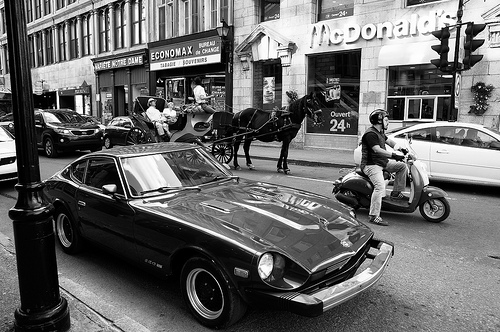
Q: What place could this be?
A: It is a city.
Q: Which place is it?
A: It is a city.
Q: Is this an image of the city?
A: Yes, it is showing the city.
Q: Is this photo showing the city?
A: Yes, it is showing the city.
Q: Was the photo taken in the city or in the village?
A: It was taken at the city.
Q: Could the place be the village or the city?
A: It is the city.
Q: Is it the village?
A: No, it is the city.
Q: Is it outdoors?
A: Yes, it is outdoors.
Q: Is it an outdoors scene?
A: Yes, it is outdoors.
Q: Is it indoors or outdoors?
A: It is outdoors.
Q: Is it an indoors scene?
A: No, it is outdoors.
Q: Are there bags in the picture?
A: No, there are no bags.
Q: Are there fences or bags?
A: No, there are no bags or fences.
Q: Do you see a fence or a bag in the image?
A: No, there are no bags or fences.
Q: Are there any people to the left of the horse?
A: Yes, there is a person to the left of the horse.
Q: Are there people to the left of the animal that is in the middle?
A: Yes, there is a person to the left of the horse.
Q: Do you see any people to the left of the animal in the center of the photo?
A: Yes, there is a person to the left of the horse.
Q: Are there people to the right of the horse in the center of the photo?
A: No, the person is to the left of the horse.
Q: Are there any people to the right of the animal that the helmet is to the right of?
A: No, the person is to the left of the horse.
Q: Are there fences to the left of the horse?
A: No, there is a person to the left of the horse.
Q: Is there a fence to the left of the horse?
A: No, there is a person to the left of the horse.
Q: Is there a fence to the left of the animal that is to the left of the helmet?
A: No, there is a person to the left of the horse.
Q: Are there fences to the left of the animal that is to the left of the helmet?
A: No, there is a person to the left of the horse.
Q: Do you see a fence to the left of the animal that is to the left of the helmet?
A: No, there is a person to the left of the horse.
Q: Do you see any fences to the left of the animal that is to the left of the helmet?
A: No, there is a person to the left of the horse.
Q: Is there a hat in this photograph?
A: Yes, there is a hat.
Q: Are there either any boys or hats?
A: Yes, there is a hat.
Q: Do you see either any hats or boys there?
A: Yes, there is a hat.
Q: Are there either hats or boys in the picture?
A: Yes, there is a hat.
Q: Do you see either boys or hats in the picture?
A: Yes, there is a hat.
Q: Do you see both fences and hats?
A: No, there is a hat but no fences.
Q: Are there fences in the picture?
A: No, there are no fences.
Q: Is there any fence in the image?
A: No, there are no fences.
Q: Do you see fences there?
A: No, there are no fences.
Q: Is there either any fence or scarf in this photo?
A: No, there are no fences or scarves.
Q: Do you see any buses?
A: No, there are no buses.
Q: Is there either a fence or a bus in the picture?
A: No, there are no buses or fences.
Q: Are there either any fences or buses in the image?
A: No, there are no buses or fences.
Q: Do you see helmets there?
A: Yes, there is a helmet.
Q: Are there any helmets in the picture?
A: Yes, there is a helmet.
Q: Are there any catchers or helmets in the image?
A: Yes, there is a helmet.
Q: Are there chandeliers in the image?
A: No, there are no chandeliers.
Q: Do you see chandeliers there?
A: No, there are no chandeliers.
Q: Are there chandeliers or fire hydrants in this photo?
A: No, there are no chandeliers or fire hydrants.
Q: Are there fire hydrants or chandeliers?
A: No, there are no chandeliers or fire hydrants.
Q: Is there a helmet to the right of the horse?
A: Yes, there is a helmet to the right of the horse.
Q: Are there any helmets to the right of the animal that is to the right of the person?
A: Yes, there is a helmet to the right of the horse.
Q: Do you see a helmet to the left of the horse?
A: No, the helmet is to the right of the horse.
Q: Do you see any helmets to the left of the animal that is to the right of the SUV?
A: No, the helmet is to the right of the horse.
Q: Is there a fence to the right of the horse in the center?
A: No, there is a helmet to the right of the horse.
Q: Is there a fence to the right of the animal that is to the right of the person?
A: No, there is a helmet to the right of the horse.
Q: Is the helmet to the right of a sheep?
A: No, the helmet is to the right of a horse.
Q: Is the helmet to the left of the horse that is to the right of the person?
A: No, the helmet is to the right of the horse.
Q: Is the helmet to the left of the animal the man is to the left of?
A: No, the helmet is to the right of the horse.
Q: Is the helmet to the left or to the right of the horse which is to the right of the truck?
A: The helmet is to the right of the horse.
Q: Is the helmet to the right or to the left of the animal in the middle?
A: The helmet is to the right of the horse.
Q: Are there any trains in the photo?
A: No, there are no trains.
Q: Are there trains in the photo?
A: No, there are no trains.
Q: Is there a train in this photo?
A: No, there are no trains.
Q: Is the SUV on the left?
A: Yes, the SUV is on the left of the image.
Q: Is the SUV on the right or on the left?
A: The SUV is on the left of the image.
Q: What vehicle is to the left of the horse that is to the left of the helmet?
A: The vehicle is a SUV.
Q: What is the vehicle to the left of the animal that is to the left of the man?
A: The vehicle is a SUV.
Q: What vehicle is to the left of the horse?
A: The vehicle is a SUV.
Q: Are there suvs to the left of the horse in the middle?
A: Yes, there is a SUV to the left of the horse.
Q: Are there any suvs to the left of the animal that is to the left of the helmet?
A: Yes, there is a SUV to the left of the horse.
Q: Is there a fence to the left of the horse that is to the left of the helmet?
A: No, there is a SUV to the left of the horse.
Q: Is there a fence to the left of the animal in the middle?
A: No, there is a SUV to the left of the horse.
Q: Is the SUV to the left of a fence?
A: No, the SUV is to the left of a horse.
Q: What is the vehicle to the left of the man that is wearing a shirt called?
A: The vehicle is a SUV.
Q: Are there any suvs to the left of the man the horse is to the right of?
A: Yes, there is a SUV to the left of the man.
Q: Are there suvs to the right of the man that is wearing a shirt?
A: No, the SUV is to the left of the man.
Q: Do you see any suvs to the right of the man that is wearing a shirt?
A: No, the SUV is to the left of the man.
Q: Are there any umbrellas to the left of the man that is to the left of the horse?
A: No, there is a SUV to the left of the man.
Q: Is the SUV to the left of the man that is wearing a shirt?
A: Yes, the SUV is to the left of the man.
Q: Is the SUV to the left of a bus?
A: No, the SUV is to the left of the man.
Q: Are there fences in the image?
A: No, there are no fences.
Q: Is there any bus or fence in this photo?
A: No, there are no fences or buses.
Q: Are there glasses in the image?
A: No, there are no glasses.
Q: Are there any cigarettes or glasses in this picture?
A: No, there are no glasses or cigarettes.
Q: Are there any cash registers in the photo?
A: No, there are no cash registers.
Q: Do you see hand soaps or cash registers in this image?
A: No, there are no cash registers or hand soaps.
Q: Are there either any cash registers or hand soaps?
A: No, there are no cash registers or hand soaps.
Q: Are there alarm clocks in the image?
A: No, there are no alarm clocks.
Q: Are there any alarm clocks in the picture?
A: No, there are no alarm clocks.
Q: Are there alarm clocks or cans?
A: No, there are no alarm clocks or cans.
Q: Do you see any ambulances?
A: No, there are no ambulances.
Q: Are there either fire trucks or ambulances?
A: No, there are no ambulances or fire trucks.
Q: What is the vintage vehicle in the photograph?
A: The vehicle is a car.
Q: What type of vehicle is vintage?
A: The vehicle is a car.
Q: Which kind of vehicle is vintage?
A: The vehicle is a car.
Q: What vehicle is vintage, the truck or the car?
A: The car is vintage.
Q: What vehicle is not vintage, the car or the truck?
A: The truck is not vintage.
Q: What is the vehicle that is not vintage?
A: The vehicle is a truck.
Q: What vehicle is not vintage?
A: The vehicle is a truck.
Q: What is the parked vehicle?
A: The vehicle is a car.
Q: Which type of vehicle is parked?
A: The vehicle is a car.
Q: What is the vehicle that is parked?
A: The vehicle is a car.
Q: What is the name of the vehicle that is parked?
A: The vehicle is a car.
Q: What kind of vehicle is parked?
A: The vehicle is a car.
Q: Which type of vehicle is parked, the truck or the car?
A: The car is parked.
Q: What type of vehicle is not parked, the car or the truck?
A: The truck is not parked.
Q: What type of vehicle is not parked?
A: The vehicle is a truck.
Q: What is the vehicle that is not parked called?
A: The vehicle is a truck.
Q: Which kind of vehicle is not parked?
A: The vehicle is a truck.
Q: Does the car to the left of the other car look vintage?
A: Yes, the car is vintage.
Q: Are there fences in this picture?
A: No, there are no fences.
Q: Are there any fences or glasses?
A: No, there are no fences or glasses.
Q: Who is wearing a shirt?
A: The man is wearing a shirt.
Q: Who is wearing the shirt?
A: The man is wearing a shirt.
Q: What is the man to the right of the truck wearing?
A: The man is wearing a shirt.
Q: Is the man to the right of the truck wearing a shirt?
A: Yes, the man is wearing a shirt.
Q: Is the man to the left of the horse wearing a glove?
A: No, the man is wearing a shirt.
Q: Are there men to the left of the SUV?
A: No, the man is to the right of the SUV.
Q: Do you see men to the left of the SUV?
A: No, the man is to the right of the SUV.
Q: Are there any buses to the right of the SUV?
A: No, there is a man to the right of the SUV.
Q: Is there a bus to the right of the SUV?
A: No, there is a man to the right of the SUV.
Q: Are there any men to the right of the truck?
A: Yes, there is a man to the right of the truck.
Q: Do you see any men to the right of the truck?
A: Yes, there is a man to the right of the truck.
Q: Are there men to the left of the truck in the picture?
A: No, the man is to the right of the truck.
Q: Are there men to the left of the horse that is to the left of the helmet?
A: Yes, there is a man to the left of the horse.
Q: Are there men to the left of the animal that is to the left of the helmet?
A: Yes, there is a man to the left of the horse.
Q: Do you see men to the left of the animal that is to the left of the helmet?
A: Yes, there is a man to the left of the horse.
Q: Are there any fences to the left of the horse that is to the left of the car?
A: No, there is a man to the left of the horse.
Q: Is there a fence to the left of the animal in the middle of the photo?
A: No, there is a man to the left of the horse.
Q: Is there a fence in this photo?
A: No, there are no fences.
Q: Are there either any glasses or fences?
A: No, there are no fences or glasses.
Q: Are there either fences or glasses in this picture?
A: No, there are no glasses or fences.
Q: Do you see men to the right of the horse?
A: Yes, there is a man to the right of the horse.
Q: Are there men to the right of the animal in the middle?
A: Yes, there is a man to the right of the horse.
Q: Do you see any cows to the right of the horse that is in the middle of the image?
A: No, there is a man to the right of the horse.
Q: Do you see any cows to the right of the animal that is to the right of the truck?
A: No, there is a man to the right of the horse.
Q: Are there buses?
A: No, there are no buses.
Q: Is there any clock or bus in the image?
A: No, there are no buses or clocks.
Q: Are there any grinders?
A: No, there are no grinders.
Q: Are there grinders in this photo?
A: No, there are no grinders.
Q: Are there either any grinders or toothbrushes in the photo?
A: No, there are no grinders or toothbrushes.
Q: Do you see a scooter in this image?
A: Yes, there is a scooter.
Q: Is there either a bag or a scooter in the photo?
A: Yes, there is a scooter.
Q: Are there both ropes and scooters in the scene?
A: No, there is a scooter but no ropes.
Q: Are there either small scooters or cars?
A: Yes, there is a small scooter.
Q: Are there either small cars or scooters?
A: Yes, there is a small scooter.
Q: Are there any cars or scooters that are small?
A: Yes, the scooter is small.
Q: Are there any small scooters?
A: Yes, there is a small scooter.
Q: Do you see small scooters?
A: Yes, there is a small scooter.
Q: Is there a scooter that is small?
A: Yes, there is a scooter that is small.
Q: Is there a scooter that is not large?
A: Yes, there is a small scooter.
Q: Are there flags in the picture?
A: No, there are no flags.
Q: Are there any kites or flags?
A: No, there are no flags or kites.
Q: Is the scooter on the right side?
A: Yes, the scooter is on the right of the image.